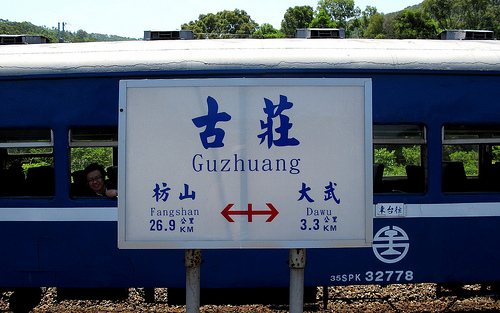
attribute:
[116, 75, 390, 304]
sign — white, gray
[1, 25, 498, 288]
train — blue, striped, white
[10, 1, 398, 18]
sky — gray